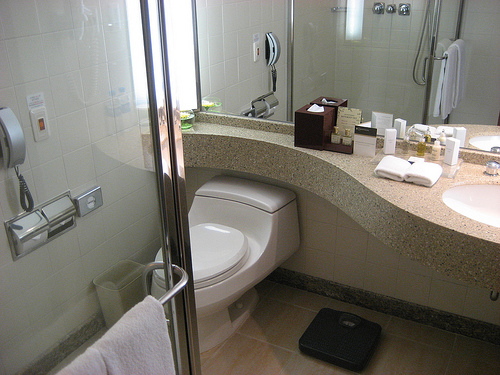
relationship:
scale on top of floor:
[297, 306, 382, 371] [200, 277, 498, 374]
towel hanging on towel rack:
[93, 294, 177, 374] [157, 265, 190, 306]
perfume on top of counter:
[330, 126, 342, 144] [142, 120, 499, 292]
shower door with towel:
[0, 0, 191, 374] [93, 294, 177, 374]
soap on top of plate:
[408, 155, 426, 165] [369, 144, 464, 180]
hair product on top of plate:
[429, 140, 440, 163] [369, 144, 464, 180]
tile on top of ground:
[201, 330, 295, 375] [200, 277, 498, 374]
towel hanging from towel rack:
[93, 294, 177, 374] [157, 265, 190, 306]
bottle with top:
[416, 136, 426, 157] [419, 137, 425, 144]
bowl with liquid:
[179, 105, 195, 130] [181, 114, 196, 130]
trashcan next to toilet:
[93, 259, 148, 331] [148, 174, 302, 353]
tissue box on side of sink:
[293, 101, 335, 151] [441, 182, 499, 230]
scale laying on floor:
[297, 306, 382, 371] [200, 277, 498, 374]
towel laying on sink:
[405, 161, 443, 188] [441, 182, 499, 230]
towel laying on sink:
[374, 155, 412, 183] [441, 182, 499, 230]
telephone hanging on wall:
[0, 105, 34, 214] [0, 1, 197, 375]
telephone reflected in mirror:
[0, 105, 34, 214] [192, 1, 500, 156]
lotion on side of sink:
[443, 136, 461, 166] [441, 182, 499, 230]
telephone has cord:
[0, 105, 34, 214] [14, 165, 34, 213]